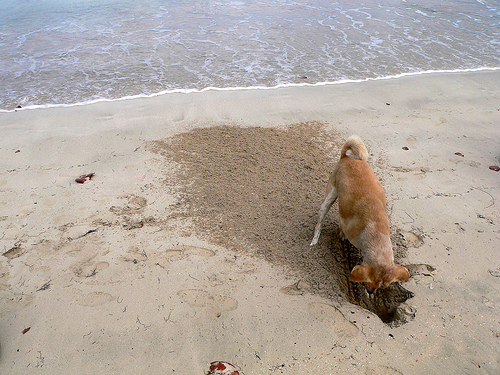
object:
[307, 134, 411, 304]
dog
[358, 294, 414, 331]
hole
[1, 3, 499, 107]
water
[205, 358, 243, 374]
red object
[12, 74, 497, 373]
sand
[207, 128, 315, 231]
sand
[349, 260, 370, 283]
ear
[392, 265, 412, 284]
ear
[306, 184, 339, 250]
leg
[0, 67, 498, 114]
edge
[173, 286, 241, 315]
prints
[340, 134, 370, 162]
tail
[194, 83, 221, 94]
foam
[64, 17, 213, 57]
wripples